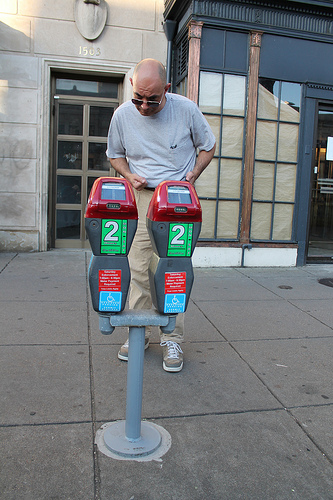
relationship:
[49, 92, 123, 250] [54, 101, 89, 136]
door with pane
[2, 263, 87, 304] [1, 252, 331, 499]
cement square on sidewalk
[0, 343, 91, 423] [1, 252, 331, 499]
cement square on sidewalk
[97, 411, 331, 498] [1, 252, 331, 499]
cement square on sidewalk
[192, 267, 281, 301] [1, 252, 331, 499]
cement square on sidewalk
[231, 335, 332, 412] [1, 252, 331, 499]
cement square on sidewalk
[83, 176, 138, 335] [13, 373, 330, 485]
meter on sidewalk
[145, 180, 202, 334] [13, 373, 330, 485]
meter on sidewalk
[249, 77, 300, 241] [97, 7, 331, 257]
windows on building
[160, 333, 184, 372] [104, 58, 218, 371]
sneaker on man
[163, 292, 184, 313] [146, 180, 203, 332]
sign on meter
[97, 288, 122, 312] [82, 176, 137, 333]
sign on meter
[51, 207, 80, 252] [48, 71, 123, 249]
pane inside door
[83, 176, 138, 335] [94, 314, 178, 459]
meter on metal post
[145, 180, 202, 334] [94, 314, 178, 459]
meter on metal post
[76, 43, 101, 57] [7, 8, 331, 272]
number on building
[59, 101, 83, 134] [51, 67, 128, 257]
pane on door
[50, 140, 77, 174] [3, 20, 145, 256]
pane on door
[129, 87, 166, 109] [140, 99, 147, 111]
glasses on nose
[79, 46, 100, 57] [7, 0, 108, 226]
1503 on building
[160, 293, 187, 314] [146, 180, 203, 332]
handicapped label on meter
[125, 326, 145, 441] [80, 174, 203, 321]
metal post of parking meter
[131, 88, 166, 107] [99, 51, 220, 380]
glasses on man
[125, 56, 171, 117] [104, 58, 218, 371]
head of man